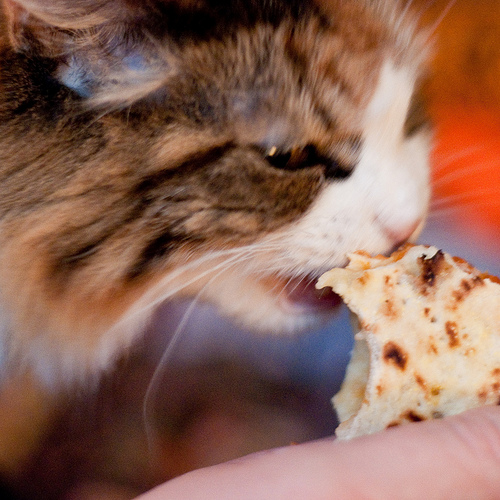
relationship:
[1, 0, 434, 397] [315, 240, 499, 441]
cat biting food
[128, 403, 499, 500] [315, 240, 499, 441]
hand holding food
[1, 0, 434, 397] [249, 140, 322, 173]
cat has eye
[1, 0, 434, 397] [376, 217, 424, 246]
cat has nose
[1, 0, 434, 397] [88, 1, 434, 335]
cat has head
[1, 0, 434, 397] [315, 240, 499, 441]
cat smelling food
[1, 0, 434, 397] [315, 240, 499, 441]
cat munching food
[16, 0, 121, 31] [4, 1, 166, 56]
hair inside of ear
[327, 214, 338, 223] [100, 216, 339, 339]
hole with whisker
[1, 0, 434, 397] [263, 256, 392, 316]
cat has mouth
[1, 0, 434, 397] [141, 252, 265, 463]
cat has whisker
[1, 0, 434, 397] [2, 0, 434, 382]
cat has fur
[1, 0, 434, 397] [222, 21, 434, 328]
cat has face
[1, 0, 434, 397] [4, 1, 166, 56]
cat has ear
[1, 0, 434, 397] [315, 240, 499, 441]
cat nibbling food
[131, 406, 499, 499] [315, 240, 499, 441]
person holding food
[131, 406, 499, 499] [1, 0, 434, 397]
person feeding cat